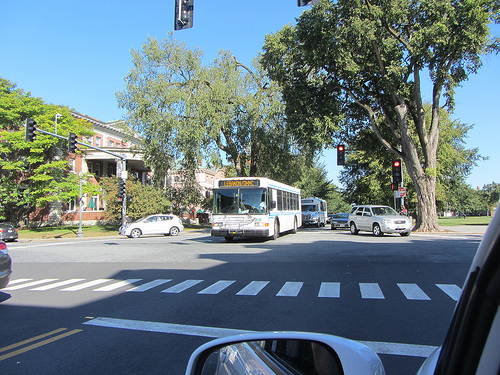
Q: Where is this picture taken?
A: A street.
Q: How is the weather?
A: Sunny.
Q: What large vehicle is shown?
A: A bus.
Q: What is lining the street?
A: Trees.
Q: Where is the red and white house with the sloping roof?
A: On the corner of the left side, of a busy, residential street.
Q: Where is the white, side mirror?
A: On a car, parked behind the horizontal, white line, fronting the crosswalk.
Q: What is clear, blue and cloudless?
A: The sky.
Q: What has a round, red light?
A: Each of the two, visible stop lights, hanging below a tall tree, over-looking the street corner, on the further side of the crosswalk.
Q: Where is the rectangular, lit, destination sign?
A: On the front of the nearest bus, on the further side of the crosswalk.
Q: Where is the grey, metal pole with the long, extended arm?
A: On the left corner of the street, behind the crosswalk.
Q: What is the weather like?
A: Sunny.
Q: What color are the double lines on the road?
A: Yellow.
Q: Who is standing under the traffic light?
A: No one.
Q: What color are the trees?
A: Green.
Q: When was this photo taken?
A: Daytime.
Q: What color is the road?
A: Grey.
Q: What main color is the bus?
A: White.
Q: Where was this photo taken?
A: At an intersection.